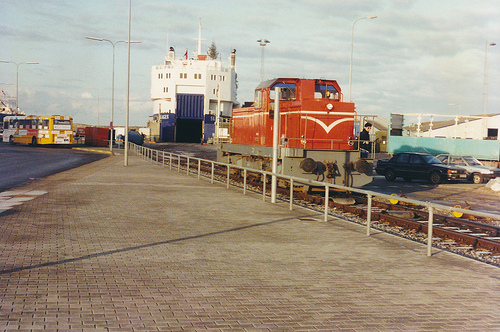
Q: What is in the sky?
A: Clouds.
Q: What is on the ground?
A: Brickwork.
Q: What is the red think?
A: Train.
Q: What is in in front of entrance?
A: White building.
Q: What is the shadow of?
A: A pole.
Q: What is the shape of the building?
A: Round.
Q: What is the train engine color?
A: Red.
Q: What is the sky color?
A: Gray clouds.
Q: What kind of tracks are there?
A: Rusted train tracks.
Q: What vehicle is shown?
A: Train.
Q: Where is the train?
A: Tracks.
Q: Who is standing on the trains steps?
A: The conductor.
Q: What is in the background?
A: Building.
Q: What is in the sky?
A: Clouds.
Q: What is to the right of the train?
A: Cars.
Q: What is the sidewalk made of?
A: Bricks.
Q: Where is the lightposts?
A: On the sidewalk.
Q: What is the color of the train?
A: Orange.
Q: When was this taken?
A: Daytime.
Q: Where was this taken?
A: A train station.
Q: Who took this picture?
A: Photographer.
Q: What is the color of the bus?
A: Yellow.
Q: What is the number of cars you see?
A: Two.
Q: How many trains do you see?
A: One.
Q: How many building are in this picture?
A: One.